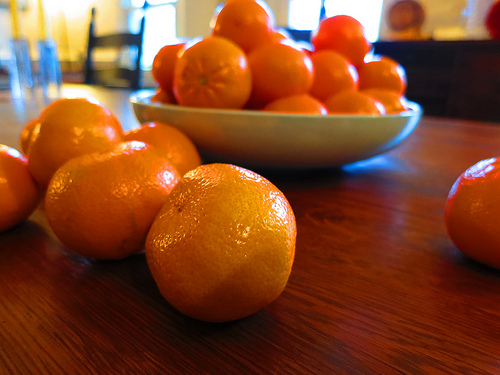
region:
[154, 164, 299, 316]
the orange is orange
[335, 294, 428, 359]
the wooden table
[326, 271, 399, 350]
a table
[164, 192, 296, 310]
the orange is on the table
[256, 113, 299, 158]
a bowl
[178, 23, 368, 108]
the oranges in a bowl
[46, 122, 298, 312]
oranges that are on the table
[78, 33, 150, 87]
a chair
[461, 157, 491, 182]
a shadow on the table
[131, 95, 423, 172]
light green round bowl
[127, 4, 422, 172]
one bowl of several oranges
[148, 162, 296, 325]
one round shiny orange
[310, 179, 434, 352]
section of brown wooden table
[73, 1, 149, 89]
dark wooden chair back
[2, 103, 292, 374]
several oranges on a wooden table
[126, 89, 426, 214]
green bowl on table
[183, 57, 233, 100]
puckered bottom of one orange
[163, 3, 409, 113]
pile of several ripe oranges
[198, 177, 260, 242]
dimpled surface of orange peel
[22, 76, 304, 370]
oranges on a table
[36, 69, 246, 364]
oranges on brown table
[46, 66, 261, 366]
oranges on wood table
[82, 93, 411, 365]
orange on a brown wood table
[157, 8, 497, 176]
oranges in a bowl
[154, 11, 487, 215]
oranges in a white bowl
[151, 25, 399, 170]
a bowl on a table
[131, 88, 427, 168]
white bowl for fruit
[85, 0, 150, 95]
chair back beside table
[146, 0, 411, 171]
tangerines in a bowl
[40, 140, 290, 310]
fruit on the table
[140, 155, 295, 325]
tangerine on the wooden table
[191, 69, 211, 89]
green stem spot on tangerine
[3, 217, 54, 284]
shadows on table from tangerines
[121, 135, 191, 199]
glare from light on tangerine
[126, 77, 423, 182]
white bowl sitting on table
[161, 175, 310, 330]
a orange in table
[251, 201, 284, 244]
light on the orange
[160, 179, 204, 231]
a part of orange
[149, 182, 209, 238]
middle of the orange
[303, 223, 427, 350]
a brown table in the floor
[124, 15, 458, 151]
a plate with oranges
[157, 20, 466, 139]
a group of oranges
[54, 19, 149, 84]
a chair on bench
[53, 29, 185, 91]
a chair on table